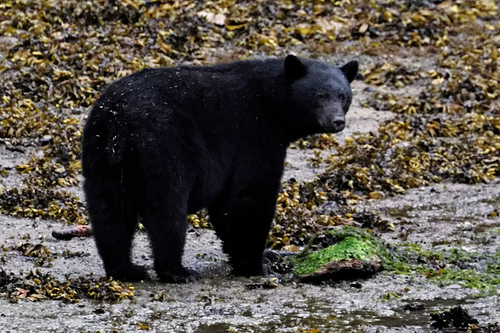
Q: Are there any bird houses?
A: No, there are no bird houses.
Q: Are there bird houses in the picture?
A: No, there are no bird houses.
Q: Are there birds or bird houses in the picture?
A: No, there are no bird houses or birds.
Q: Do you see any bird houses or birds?
A: No, there are no bird houses or birds.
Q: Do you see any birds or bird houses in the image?
A: No, there are no bird houses or birds.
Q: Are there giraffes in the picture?
A: No, there are no giraffes.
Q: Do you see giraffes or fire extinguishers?
A: No, there are no giraffes or fire extinguishers.